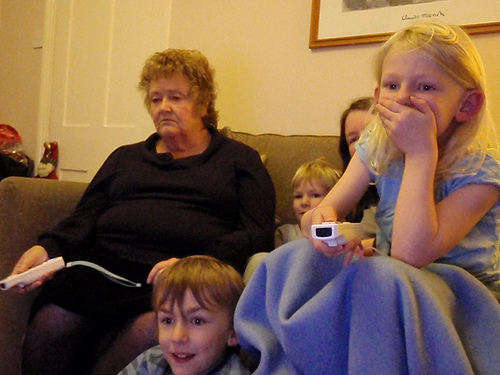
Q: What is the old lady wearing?
A: Black shirt.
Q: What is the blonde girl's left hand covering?
A: Mouth.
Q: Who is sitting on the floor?
A: Young boy.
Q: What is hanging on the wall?
A: A picture.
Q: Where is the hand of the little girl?
A: Over her mouth.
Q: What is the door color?
A: White.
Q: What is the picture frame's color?
A: Brown.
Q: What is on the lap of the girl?
A: Blanket.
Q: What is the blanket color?
A: Blue.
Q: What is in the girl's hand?
A: Video game controller.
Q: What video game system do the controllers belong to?
A: Wii.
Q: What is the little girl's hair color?
A: Blonde.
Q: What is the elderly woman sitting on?
A: Couch.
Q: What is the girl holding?
A: A Wii controller.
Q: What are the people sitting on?
A: A couch.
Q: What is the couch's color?
A: Brown.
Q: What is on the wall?
A: A framed poster.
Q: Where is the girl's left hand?
A: Over her mouth.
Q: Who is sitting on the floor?
A: The boy.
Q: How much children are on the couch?
A: Two.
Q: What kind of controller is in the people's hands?
A: Wii controller.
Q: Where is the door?
A: To the right of the woman.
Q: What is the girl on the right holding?
A: Remote control.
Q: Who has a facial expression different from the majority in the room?
A: Woman in black dress.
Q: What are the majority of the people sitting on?
A: Sofa.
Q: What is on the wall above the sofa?
A: Framed painting.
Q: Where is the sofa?
A: Living room.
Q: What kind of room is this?
A: Living room.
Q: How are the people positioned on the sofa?
A: Side by side.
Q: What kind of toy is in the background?
A: Stuffed doll.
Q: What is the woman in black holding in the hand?
A: Video game controller.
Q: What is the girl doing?
A: Covering her mouth.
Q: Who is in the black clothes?
A: An old lady.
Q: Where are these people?
A: In a living room.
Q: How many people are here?
A: Five.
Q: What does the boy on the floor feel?
A: Surprise.